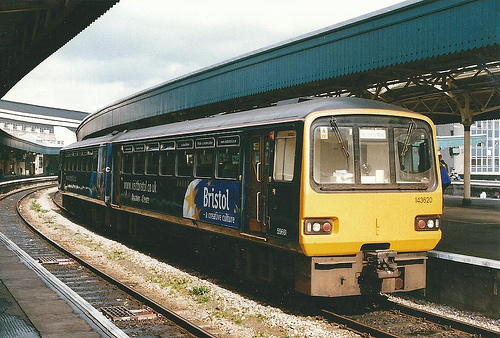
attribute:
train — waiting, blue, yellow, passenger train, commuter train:
[44, 101, 448, 309]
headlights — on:
[304, 209, 444, 234]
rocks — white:
[105, 228, 321, 335]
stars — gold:
[182, 180, 202, 218]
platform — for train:
[2, 133, 60, 191]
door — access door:
[241, 131, 276, 230]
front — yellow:
[298, 97, 444, 300]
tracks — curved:
[1, 174, 452, 337]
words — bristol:
[199, 184, 234, 208]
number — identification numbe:
[413, 194, 435, 206]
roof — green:
[76, 3, 499, 138]